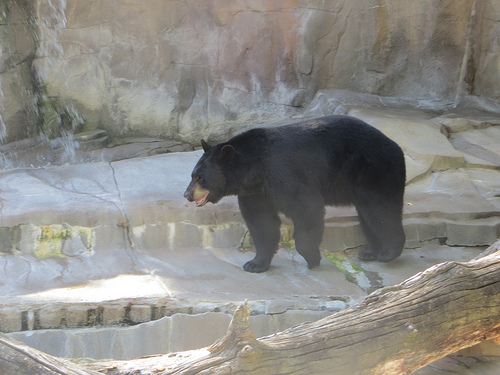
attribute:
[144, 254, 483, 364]
log — Large wooden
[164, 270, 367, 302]
surface — stone 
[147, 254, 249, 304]
surface — stone 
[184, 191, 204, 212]
mouth — open, bear's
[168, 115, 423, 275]
bear — black , walking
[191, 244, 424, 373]
log — Large 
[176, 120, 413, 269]
bear — rear, black 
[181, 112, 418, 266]
bear — rear, black , walking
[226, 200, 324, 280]
legs — two front 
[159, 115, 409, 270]
bear — black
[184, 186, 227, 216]
tongue — pink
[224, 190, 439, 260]
legs — short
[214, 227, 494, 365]
log — long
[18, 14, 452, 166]
wall — rock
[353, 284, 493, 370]
log — green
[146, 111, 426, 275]
bear — black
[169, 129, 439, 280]
bear — walking